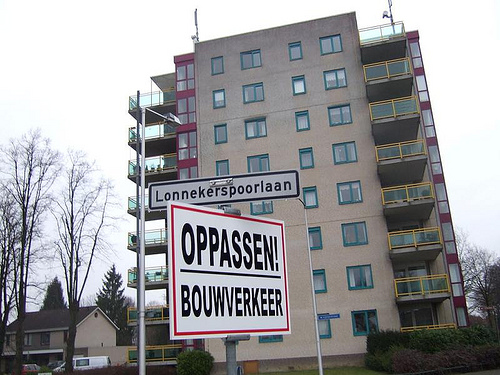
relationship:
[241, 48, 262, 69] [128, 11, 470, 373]
window on building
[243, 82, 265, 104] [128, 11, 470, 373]
window on building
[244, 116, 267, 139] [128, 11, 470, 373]
window on building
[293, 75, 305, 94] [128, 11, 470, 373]
window on building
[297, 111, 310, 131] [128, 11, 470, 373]
window on building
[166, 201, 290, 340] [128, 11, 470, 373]
sign in front of building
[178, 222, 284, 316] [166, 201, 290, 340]
letters printed on sign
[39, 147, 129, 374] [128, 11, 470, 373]
tree to left of building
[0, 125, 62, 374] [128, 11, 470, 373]
tree to left of building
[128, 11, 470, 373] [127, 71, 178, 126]
building has balcony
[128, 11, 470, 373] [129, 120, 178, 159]
building has balcony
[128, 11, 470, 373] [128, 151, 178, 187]
building has balcony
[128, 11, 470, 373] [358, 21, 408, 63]
building has balcony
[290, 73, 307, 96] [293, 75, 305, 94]
window around window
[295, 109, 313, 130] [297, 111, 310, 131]
trim around window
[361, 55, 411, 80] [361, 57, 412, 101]
trim on balcony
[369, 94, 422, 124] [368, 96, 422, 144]
trim on balcony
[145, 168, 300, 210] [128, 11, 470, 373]
sign in front of building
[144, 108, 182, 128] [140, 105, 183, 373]
street light attached to light pole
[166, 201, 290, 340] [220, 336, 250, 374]
sign attached to post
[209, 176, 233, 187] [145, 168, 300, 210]
bracket attached to sign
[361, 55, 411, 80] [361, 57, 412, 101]
trim around balcony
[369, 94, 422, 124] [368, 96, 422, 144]
trim around balcony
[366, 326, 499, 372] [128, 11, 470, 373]
bush next to building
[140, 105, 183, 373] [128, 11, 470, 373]
light pole in front of building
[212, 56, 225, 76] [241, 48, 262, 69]
window next to window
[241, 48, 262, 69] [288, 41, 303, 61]
window next to window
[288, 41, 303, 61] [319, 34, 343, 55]
window next to window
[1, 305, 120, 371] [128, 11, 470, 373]
house to left of building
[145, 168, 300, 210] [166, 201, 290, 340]
sign above sign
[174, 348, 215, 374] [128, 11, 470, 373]
bush in front of building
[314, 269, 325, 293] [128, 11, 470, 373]
window visible on building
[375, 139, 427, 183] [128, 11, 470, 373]
balcony visible on building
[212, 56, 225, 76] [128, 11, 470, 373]
window on building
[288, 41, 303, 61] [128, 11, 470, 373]
window on building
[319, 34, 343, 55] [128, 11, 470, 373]
window on building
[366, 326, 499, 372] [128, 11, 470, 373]
bush in front of building